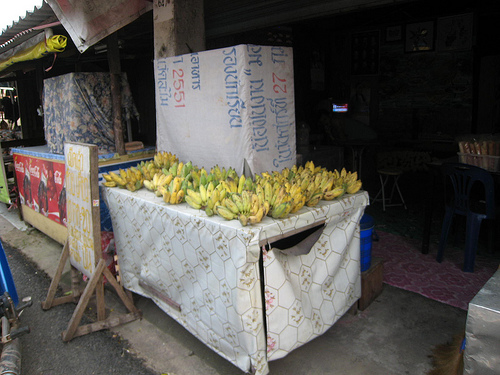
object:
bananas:
[234, 210, 252, 227]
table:
[103, 161, 370, 374]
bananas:
[205, 180, 214, 194]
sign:
[43, 141, 144, 342]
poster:
[11, 153, 67, 228]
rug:
[372, 196, 500, 310]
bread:
[459, 136, 498, 169]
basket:
[455, 136, 499, 173]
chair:
[372, 166, 408, 212]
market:
[0, 0, 499, 373]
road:
[0, 239, 243, 374]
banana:
[152, 172, 159, 189]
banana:
[184, 194, 202, 210]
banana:
[249, 204, 264, 224]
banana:
[105, 170, 127, 187]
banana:
[176, 160, 184, 178]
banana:
[323, 184, 343, 200]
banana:
[197, 182, 206, 198]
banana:
[101, 181, 118, 187]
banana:
[289, 193, 307, 213]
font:
[223, 46, 292, 167]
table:
[10, 139, 158, 250]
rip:
[263, 220, 328, 258]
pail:
[359, 216, 374, 273]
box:
[358, 249, 387, 311]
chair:
[420, 161, 499, 273]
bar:
[234, 45, 295, 310]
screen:
[331, 99, 349, 113]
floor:
[0, 205, 467, 374]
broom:
[428, 336, 464, 374]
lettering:
[172, 67, 187, 110]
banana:
[341, 166, 347, 178]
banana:
[333, 168, 340, 177]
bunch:
[213, 207, 230, 225]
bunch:
[184, 185, 200, 205]